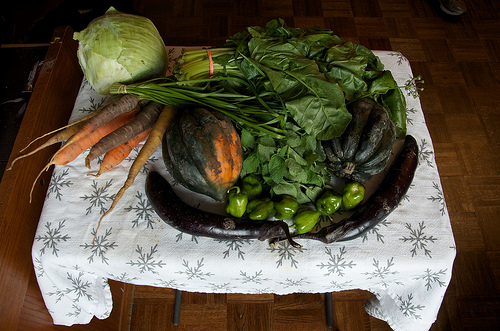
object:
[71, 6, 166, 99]
lettuce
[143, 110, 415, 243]
vegetable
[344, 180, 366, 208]
pepper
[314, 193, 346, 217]
pepper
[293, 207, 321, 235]
pepper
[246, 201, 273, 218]
pepper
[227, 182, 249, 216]
pepper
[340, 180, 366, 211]
peppers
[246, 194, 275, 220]
peppers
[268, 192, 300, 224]
peppers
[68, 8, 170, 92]
cabbage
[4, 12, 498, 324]
table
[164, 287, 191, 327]
table leg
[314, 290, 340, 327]
table leg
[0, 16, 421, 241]
vegetables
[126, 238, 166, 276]
snowflake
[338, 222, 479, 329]
towel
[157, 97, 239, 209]
squash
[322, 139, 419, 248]
eggplant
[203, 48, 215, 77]
ribbon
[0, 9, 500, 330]
wooden squares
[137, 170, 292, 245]
purple eggplant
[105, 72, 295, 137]
onion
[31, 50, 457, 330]
tablecloth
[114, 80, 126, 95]
bands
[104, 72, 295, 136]
scallions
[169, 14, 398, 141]
spinach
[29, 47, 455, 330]
cloth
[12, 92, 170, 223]
carrots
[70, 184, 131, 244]
roots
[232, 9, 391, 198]
leaves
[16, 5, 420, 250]
fruit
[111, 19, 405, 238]
greens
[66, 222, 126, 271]
snowflake pattern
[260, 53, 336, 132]
center stem